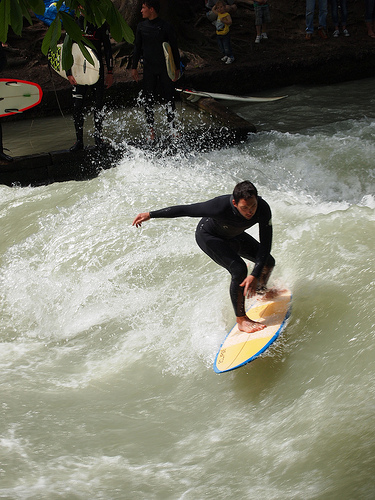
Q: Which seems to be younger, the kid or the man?
A: The kid is younger than the man.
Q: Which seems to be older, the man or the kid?
A: The man is older than the kid.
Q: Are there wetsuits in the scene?
A: Yes, there is a wetsuit.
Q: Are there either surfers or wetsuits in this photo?
A: Yes, there is a wetsuit.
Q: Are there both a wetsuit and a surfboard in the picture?
A: Yes, there are both a wetsuit and a surfboard.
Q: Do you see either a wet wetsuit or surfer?
A: Yes, there is a wet wetsuit.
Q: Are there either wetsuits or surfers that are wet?
A: Yes, the wetsuit is wet.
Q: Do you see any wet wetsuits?
A: Yes, there is a wet wetsuit.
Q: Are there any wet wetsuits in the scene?
A: Yes, there is a wet wetsuit.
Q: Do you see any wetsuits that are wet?
A: Yes, there is a wet wetsuit.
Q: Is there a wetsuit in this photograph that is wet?
A: Yes, there is a wetsuit that is wet.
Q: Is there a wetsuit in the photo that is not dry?
A: Yes, there is a wet wetsuit.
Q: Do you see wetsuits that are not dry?
A: Yes, there is a wet wetsuit.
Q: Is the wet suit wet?
A: Yes, the wet suit is wet.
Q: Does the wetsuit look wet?
A: Yes, the wetsuit is wet.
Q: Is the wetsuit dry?
A: No, the wetsuit is wet.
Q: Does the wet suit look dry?
A: No, the wet suit is wet.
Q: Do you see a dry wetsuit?
A: No, there is a wetsuit but it is wet.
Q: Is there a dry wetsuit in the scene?
A: No, there is a wetsuit but it is wet.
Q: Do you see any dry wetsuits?
A: No, there is a wetsuit but it is wet.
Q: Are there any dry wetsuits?
A: No, there is a wetsuit but it is wet.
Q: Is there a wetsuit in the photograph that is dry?
A: No, there is a wetsuit but it is wet.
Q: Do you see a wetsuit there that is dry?
A: No, there is a wetsuit but it is wet.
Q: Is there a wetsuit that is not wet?
A: No, there is a wetsuit but it is wet.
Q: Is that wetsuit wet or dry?
A: The wetsuit is wet.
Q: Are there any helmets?
A: No, there are no helmets.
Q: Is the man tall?
A: Yes, the man is tall.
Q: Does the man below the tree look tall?
A: Yes, the man is tall.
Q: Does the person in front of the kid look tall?
A: Yes, the man is tall.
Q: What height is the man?
A: The man is tall.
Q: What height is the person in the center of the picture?
A: The man is tall.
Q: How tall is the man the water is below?
A: The man is tall.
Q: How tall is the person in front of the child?
A: The man is tall.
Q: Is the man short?
A: No, the man is tall.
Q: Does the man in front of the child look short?
A: No, the man is tall.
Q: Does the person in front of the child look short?
A: No, the man is tall.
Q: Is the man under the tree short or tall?
A: The man is tall.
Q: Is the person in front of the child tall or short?
A: The man is tall.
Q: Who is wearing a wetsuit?
A: The man is wearing a wetsuit.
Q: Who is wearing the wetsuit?
A: The man is wearing a wetsuit.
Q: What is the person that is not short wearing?
A: The man is wearing a wetsuit.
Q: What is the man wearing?
A: The man is wearing a wetsuit.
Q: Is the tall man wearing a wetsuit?
A: Yes, the man is wearing a wetsuit.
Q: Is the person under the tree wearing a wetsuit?
A: Yes, the man is wearing a wetsuit.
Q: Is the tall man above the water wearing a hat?
A: No, the man is wearing a wetsuit.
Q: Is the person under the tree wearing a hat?
A: No, the man is wearing a wetsuit.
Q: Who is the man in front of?
A: The man is in front of the kid.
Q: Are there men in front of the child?
A: Yes, there is a man in front of the child.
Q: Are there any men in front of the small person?
A: Yes, there is a man in front of the child.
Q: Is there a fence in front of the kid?
A: No, there is a man in front of the kid.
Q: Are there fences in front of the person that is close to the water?
A: No, there is a man in front of the kid.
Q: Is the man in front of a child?
A: Yes, the man is in front of a child.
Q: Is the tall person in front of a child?
A: Yes, the man is in front of a child.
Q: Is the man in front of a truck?
A: No, the man is in front of a child.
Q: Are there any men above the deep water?
A: Yes, there is a man above the water.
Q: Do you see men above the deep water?
A: Yes, there is a man above the water.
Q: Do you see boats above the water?
A: No, there is a man above the water.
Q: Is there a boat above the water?
A: No, there is a man above the water.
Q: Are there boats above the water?
A: No, there is a man above the water.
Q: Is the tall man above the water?
A: Yes, the man is above the water.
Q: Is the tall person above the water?
A: Yes, the man is above the water.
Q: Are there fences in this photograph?
A: No, there are no fences.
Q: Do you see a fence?
A: No, there are no fences.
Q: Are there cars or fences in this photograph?
A: No, there are no fences or cars.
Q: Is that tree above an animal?
A: No, the tree is above a surfboard.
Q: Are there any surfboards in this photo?
A: Yes, there is a surfboard.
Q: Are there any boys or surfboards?
A: Yes, there is a surfboard.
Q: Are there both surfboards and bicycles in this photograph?
A: No, there is a surfboard but no bikes.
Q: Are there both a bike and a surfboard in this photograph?
A: No, there is a surfboard but no bikes.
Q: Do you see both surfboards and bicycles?
A: No, there is a surfboard but no bikes.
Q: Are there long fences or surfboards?
A: Yes, there is a long surfboard.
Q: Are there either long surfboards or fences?
A: Yes, there is a long surfboard.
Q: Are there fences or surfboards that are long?
A: Yes, the surfboard is long.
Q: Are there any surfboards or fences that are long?
A: Yes, the surfboard is long.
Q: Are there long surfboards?
A: Yes, there is a long surfboard.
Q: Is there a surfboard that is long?
A: Yes, there is a surfboard that is long.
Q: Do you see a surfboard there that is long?
A: Yes, there is a surfboard that is long.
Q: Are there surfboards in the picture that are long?
A: Yes, there is a surfboard that is long.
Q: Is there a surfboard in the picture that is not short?
A: Yes, there is a long surfboard.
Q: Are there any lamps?
A: No, there are no lamps.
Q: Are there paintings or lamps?
A: No, there are no lamps or paintings.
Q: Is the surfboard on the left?
A: Yes, the surfboard is on the left of the image.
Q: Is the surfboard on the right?
A: No, the surfboard is on the left of the image.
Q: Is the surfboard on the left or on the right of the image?
A: The surfboard is on the left of the image.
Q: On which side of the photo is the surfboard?
A: The surfboard is on the left of the image.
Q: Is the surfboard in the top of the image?
A: Yes, the surfboard is in the top of the image.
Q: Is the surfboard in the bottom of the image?
A: No, the surfboard is in the top of the image.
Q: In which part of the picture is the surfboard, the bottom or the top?
A: The surfboard is in the top of the image.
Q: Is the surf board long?
A: Yes, the surf board is long.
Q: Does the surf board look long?
A: Yes, the surf board is long.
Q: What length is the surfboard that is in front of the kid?
A: The surfboard is long.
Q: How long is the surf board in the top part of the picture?
A: The surfboard is long.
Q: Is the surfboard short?
A: No, the surfboard is long.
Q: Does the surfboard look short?
A: No, the surfboard is long.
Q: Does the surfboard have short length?
A: No, the surfboard is long.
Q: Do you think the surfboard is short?
A: No, the surfboard is long.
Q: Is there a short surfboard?
A: No, there is a surfboard but it is long.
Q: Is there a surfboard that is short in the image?
A: No, there is a surfboard but it is long.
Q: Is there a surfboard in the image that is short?
A: No, there is a surfboard but it is long.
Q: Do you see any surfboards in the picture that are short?
A: No, there is a surfboard but it is long.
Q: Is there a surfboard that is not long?
A: No, there is a surfboard but it is long.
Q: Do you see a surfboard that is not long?
A: No, there is a surfboard but it is long.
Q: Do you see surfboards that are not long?
A: No, there is a surfboard but it is long.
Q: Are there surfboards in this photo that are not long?
A: No, there is a surfboard but it is long.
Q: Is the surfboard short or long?
A: The surfboard is long.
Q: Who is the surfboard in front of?
A: The surfboard is in front of the child.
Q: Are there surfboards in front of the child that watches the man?
A: Yes, there is a surfboard in front of the child.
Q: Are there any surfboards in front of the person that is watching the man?
A: Yes, there is a surfboard in front of the child.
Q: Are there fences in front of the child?
A: No, there is a surfboard in front of the child.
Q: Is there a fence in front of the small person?
A: No, there is a surfboard in front of the child.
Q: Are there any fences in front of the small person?
A: No, there is a surfboard in front of the child.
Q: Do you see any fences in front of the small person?
A: No, there is a surfboard in front of the child.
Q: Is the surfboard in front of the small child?
A: Yes, the surfboard is in front of the kid.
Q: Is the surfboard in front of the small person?
A: Yes, the surfboard is in front of the kid.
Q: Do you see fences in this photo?
A: No, there are no fences.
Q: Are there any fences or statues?
A: No, there are no fences or statues.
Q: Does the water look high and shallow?
A: No, the water is high but deep.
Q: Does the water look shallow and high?
A: No, the water is high but deep.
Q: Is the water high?
A: Yes, the water is high.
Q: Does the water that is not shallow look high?
A: Yes, the water is high.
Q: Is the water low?
A: No, the water is high.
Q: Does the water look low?
A: No, the water is high.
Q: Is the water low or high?
A: The water is high.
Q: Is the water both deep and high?
A: Yes, the water is deep and high.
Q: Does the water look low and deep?
A: No, the water is deep but high.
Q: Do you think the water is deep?
A: Yes, the water is deep.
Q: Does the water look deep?
A: Yes, the water is deep.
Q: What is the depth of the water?
A: The water is deep.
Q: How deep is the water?
A: The water is deep.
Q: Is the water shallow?
A: No, the water is deep.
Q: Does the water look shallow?
A: No, the water is deep.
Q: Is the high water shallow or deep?
A: The water is deep.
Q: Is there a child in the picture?
A: Yes, there is a child.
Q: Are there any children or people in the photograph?
A: Yes, there is a child.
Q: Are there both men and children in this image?
A: Yes, there are both a child and a man.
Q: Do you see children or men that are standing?
A: Yes, the child is standing.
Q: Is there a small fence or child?
A: Yes, there is a small child.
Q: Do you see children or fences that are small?
A: Yes, the child is small.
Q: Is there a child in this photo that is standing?
A: Yes, there is a child that is standing.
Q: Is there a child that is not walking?
A: Yes, there is a child that is standing.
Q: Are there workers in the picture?
A: No, there are no workers.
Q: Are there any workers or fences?
A: No, there are no workers or fences.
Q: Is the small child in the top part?
A: Yes, the kid is in the top of the image.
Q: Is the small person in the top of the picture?
A: Yes, the kid is in the top of the image.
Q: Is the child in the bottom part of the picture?
A: No, the child is in the top of the image.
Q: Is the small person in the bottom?
A: No, the child is in the top of the image.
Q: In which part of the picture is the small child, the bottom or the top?
A: The kid is in the top of the image.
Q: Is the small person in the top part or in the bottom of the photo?
A: The kid is in the top of the image.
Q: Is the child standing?
A: Yes, the child is standing.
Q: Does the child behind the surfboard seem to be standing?
A: Yes, the child is standing.